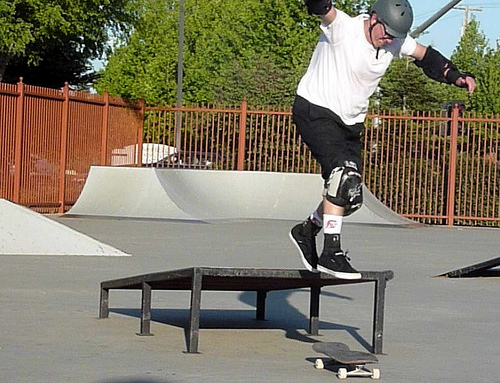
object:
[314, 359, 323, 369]
wheel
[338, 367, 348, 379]
wheel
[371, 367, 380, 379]
wheel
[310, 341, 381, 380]
skateboard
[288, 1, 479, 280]
man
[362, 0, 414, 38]
helmet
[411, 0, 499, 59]
sky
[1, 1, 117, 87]
tree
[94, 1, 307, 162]
tree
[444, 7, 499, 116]
tree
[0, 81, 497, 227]
fence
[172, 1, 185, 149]
pole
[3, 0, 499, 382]
park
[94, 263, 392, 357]
ramp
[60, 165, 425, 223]
ramp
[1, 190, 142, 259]
ramp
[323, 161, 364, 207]
knee pads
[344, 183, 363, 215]
knee pads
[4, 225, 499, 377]
floor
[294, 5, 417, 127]
shirt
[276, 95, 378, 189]
shorts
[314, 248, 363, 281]
shoes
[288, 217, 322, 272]
shoes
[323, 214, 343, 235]
socks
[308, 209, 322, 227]
socks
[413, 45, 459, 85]
arm pads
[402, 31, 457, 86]
arm